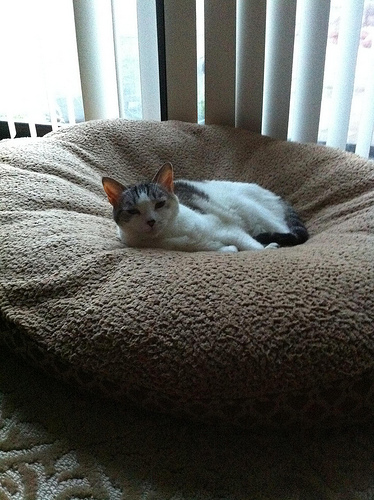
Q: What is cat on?
A: Bed.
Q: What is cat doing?
A: Laying down.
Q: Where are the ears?
A: On cat.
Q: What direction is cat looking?
A: Straight.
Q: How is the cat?
A: Curled.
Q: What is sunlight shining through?
A: Blinds.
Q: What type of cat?
A: Tabby.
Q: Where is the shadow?
A: On carpet.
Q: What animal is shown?
A: Cat.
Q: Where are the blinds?
A: On the window.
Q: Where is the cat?
A: On the pillow.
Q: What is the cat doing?
A: Resting.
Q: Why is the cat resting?
A: He is tired.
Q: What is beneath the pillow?
A: Carpet.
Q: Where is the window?
A: Behind the cat.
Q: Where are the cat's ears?
A: On its head.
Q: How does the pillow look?
A: Soft.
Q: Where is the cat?
A: On the cat bed.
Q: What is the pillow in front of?
A: The window.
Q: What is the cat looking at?
A: The camera.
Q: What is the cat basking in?
A: The sun from the window.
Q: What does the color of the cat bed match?
A: The carpet.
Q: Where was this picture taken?
A: Inside a dwelling.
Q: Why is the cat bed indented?
A: The cat is laying on it.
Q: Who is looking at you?
A: The cat.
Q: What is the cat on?
A: A pet bed.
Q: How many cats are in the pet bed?
A: 1.